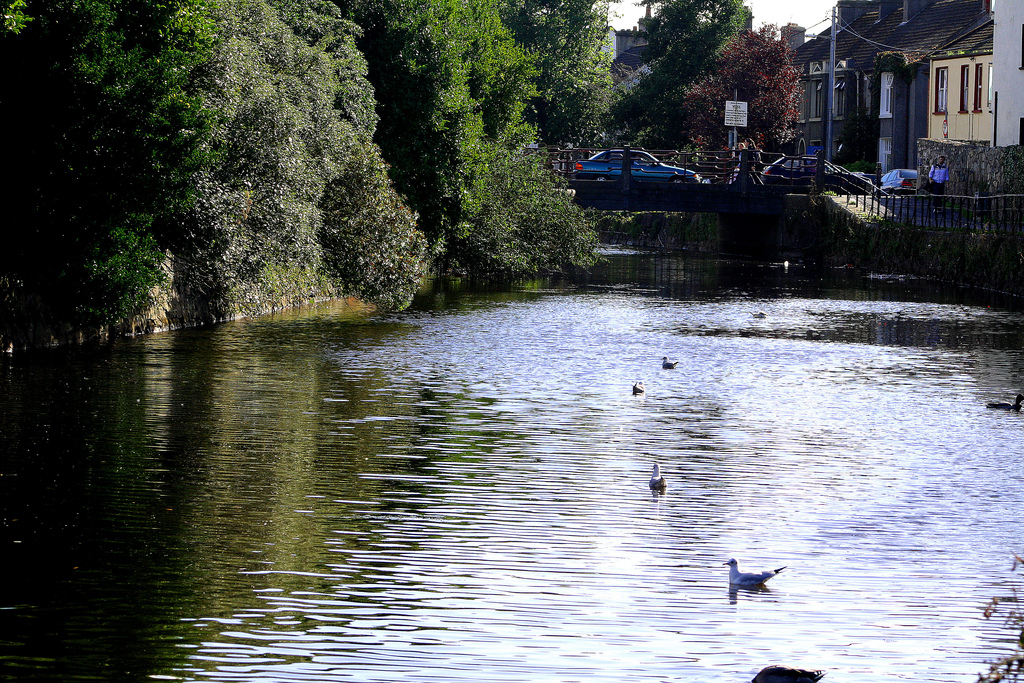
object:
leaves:
[472, 198, 595, 280]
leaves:
[0, 0, 199, 316]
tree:
[367, 0, 523, 229]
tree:
[190, 0, 376, 266]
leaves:
[194, 0, 365, 300]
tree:
[0, 0, 218, 337]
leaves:
[365, 2, 524, 225]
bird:
[723, 558, 787, 586]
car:
[575, 149, 699, 183]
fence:
[542, 148, 823, 187]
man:
[929, 156, 949, 213]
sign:
[725, 100, 748, 126]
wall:
[916, 138, 1016, 196]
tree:
[686, 32, 797, 146]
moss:
[879, 241, 957, 269]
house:
[785, 0, 1017, 196]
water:
[13, 218, 1021, 676]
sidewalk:
[860, 196, 1023, 232]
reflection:
[206, 336, 311, 562]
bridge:
[532, 151, 782, 212]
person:
[744, 138, 763, 184]